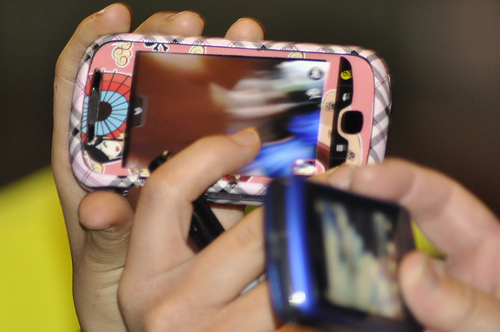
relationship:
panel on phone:
[317, 53, 370, 168] [68, 11, 403, 215]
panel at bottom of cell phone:
[326, 53, 362, 171] [65, 20, 392, 209]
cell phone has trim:
[65, 20, 392, 209] [74, 29, 395, 198]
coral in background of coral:
[220, 78, 314, 171] [131, 52, 328, 177]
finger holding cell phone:
[49, 3, 130, 252] [65, 20, 392, 209]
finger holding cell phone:
[130, 9, 203, 39] [65, 20, 392, 209]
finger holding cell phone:
[224, 16, 264, 42] [65, 20, 392, 209]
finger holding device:
[76, 190, 133, 265] [68, 39, 394, 206]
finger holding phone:
[127, 126, 262, 268] [47, 23, 405, 198]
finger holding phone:
[289, 131, 457, 215] [78, 30, 435, 225]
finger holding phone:
[352, 157, 498, 287] [69, 30, 392, 203]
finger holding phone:
[101, 117, 238, 247] [76, 32, 404, 181]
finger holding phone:
[222, 9, 262, 49] [46, 24, 437, 235]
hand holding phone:
[38, 21, 484, 318] [78, 30, 435, 225]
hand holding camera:
[339, 151, 494, 330] [264, 176, 424, 332]